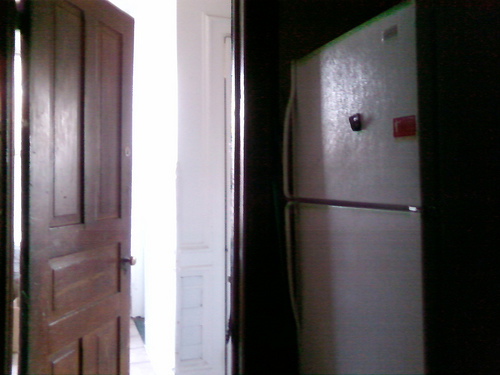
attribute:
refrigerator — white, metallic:
[274, 3, 499, 372]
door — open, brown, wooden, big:
[18, 1, 142, 372]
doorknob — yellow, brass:
[118, 250, 141, 272]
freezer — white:
[273, 1, 499, 215]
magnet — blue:
[341, 104, 370, 138]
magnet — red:
[389, 112, 420, 141]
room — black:
[229, 1, 499, 372]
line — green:
[286, 0, 419, 70]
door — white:
[172, 2, 239, 374]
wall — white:
[110, 1, 177, 373]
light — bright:
[133, 2, 178, 374]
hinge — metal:
[12, 4, 25, 35]